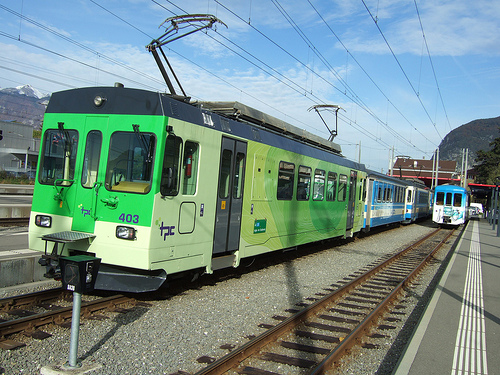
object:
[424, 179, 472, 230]
train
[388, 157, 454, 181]
roof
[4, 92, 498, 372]
train station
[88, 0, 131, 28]
power lines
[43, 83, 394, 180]
black top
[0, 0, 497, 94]
blue sky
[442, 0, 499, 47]
clouds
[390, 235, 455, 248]
tracks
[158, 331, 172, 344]
gravel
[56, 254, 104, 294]
signal box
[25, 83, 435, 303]
commuter train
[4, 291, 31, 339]
track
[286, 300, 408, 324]
train tracks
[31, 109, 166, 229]
front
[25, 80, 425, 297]
train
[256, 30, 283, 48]
wires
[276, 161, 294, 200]
windows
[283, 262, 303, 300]
shadow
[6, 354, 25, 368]
gray gravel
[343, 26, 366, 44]
white clouds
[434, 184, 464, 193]
blue top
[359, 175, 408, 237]
train car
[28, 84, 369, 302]
green train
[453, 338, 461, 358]
white lines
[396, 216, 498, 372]
pedestrian walkway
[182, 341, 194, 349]
grey gravels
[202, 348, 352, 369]
railroad tracks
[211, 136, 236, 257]
doors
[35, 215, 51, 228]
headlights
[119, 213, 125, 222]
number 4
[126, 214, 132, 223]
0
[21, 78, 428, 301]
trolley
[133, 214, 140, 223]
number 3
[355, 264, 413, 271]
tracks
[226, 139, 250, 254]
doors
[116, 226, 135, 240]
headlight